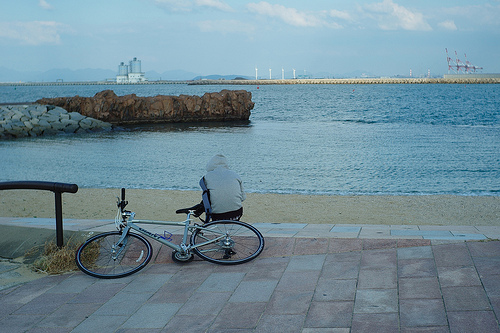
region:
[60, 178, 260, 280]
bicycle laying on walkway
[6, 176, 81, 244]
black railing on walkway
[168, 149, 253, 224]
person sitting on edge of walkway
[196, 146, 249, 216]
grey hooded jacket of person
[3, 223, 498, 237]
gray edge of walkway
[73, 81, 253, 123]
cliff in ocean water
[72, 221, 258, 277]
tires of bicycle laying on walkway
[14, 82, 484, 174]
ocean in front of person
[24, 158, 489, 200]
ocean water lapping the sand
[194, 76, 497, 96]
strip of land in distance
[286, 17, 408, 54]
this is the sky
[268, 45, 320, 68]
the sky is blue in color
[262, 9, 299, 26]
these are the clouds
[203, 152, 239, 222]
this is a man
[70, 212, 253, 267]
this is a bicycle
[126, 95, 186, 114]
this is a rock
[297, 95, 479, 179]
this is a water body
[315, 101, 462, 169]
the water is calm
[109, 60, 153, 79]
this is a building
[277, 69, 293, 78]
this is a pole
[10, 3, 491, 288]
bicyclist stopped at ocean edge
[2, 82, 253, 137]
blocks of gray and brown rocks forming barrier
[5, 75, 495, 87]
narrow strips of tan land across water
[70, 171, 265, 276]
black bicycle laying on its side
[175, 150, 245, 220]
person crouched down on sand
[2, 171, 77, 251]
black curved railing by sand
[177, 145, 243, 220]
person wearing gray hooded sweatshirt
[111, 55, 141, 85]
round buildings on top of flat buildings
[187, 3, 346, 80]
large white poles under blue sky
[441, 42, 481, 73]
vertical and horizontal structure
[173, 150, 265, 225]
A man sitting on the beach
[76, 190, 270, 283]
A bicycle lying down by the beach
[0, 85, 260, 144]
A rocking jutting into the water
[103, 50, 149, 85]
Buildings in the background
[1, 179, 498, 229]
A sandy beach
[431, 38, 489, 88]
Red and white wind terbines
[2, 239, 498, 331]
A stone path along the beach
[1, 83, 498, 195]
A large body of water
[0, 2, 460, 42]
Clouds in the sky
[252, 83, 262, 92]
A lone bird flying over the water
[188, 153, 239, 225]
A person sitting by a bicycle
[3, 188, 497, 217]
Sand by the water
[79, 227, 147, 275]
The front tire of the bicycle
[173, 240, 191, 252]
A pedal on the bicycle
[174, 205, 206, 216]
The black seat of the bicycle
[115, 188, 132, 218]
Handlebars of the bicycle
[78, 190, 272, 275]
A bicycle on the ground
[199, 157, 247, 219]
A person in a white hoodie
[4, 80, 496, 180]
Blue water below the sky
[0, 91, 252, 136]
A stone pier above the water